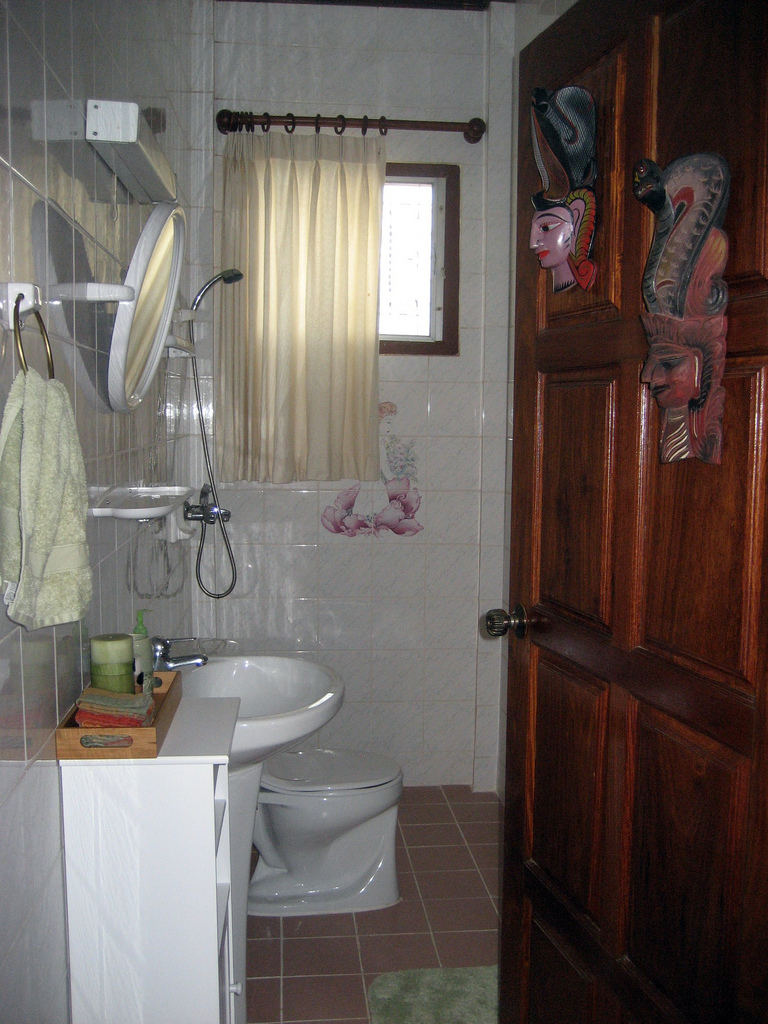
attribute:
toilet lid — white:
[261, 749, 411, 793]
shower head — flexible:
[174, 260, 266, 606]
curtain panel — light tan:
[216, 123, 389, 494]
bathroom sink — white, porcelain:
[163, 637, 327, 899]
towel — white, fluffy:
[1, 368, 88, 630]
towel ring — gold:
[13, 292, 56, 378]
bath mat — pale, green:
[364, 961, 499, 1022]